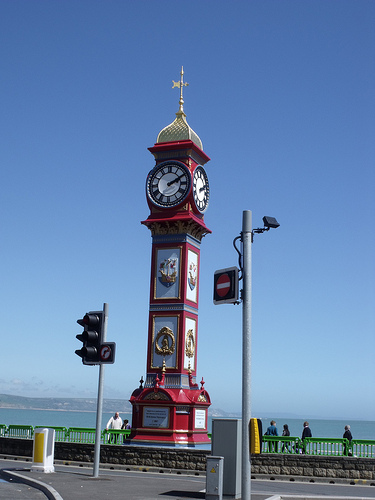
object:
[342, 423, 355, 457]
people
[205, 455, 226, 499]
box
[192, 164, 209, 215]
clock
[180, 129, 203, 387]
side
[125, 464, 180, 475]
curb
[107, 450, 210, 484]
sidewalk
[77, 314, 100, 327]
light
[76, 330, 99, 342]
light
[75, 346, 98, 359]
light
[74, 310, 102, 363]
signal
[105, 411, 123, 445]
man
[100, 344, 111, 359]
traffic signal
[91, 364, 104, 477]
post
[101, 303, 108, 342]
post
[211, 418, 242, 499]
boxes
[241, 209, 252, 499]
pole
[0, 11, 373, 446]
horizon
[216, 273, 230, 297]
circle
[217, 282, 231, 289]
line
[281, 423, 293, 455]
person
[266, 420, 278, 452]
person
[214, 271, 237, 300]
sign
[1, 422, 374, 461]
fence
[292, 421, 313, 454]
people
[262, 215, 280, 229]
rectangular box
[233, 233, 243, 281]
wire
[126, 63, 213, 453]
tower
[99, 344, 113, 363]
sign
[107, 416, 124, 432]
sweater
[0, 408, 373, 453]
water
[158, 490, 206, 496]
shadow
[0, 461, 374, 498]
ground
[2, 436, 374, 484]
wall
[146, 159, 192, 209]
clock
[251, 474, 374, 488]
road curb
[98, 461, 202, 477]
road curb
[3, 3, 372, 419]
sky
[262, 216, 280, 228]
solar panel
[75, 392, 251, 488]
bridge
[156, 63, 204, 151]
spire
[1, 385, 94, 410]
mountain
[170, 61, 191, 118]
tool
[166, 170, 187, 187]
2:10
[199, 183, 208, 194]
2:10